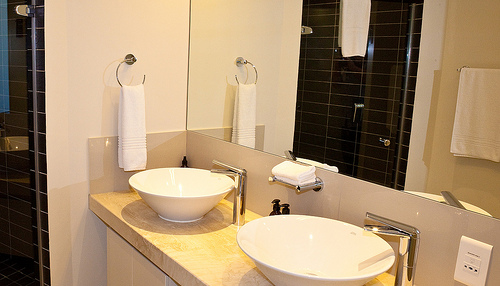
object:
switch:
[452, 233, 492, 286]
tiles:
[299, 64, 339, 137]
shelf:
[265, 178, 326, 196]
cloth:
[118, 86, 148, 172]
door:
[286, 0, 428, 190]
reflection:
[230, 83, 256, 148]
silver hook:
[232, 55, 258, 85]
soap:
[270, 161, 318, 188]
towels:
[271, 160, 317, 185]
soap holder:
[269, 175, 324, 194]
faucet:
[211, 159, 248, 223]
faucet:
[366, 211, 421, 284]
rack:
[113, 52, 147, 88]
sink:
[236, 212, 396, 285]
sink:
[129, 166, 235, 224]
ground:
[410, 98, 433, 120]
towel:
[334, 3, 374, 61]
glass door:
[296, 0, 426, 196]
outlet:
[453, 235, 494, 286]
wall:
[43, 0, 500, 286]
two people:
[116, 82, 149, 172]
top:
[270, 199, 280, 204]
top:
[280, 203, 290, 207]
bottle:
[269, 199, 281, 216]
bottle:
[280, 203, 290, 214]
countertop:
[91, 186, 420, 286]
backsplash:
[184, 131, 499, 285]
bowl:
[129, 166, 238, 224]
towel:
[448, 69, 500, 165]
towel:
[118, 85, 149, 172]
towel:
[232, 81, 256, 150]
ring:
[121, 53, 140, 66]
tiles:
[0, 1, 53, 286]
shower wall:
[28, 2, 195, 286]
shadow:
[129, 199, 233, 234]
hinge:
[351, 103, 365, 123]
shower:
[0, 2, 52, 283]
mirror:
[188, 0, 500, 217]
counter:
[86, 190, 413, 286]